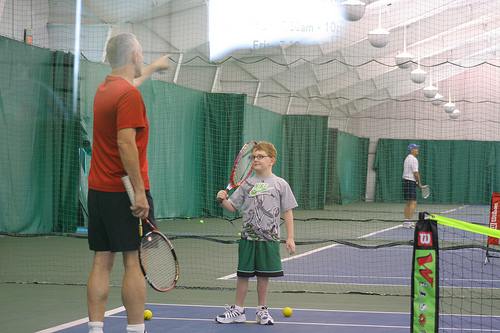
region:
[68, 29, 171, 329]
An older man wearing a red shirt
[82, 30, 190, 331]
A man holding a tennis racket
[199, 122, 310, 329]
a young boy holding a tennis racket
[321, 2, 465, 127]
a row of globe lights across a white ceiling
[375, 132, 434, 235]
a man in a white shirt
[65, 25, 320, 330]
an older man teaching a youngster about tennis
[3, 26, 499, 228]
green tarp draped along the walls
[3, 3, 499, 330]
netting forms a wall seperating areas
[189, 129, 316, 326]
a young boy with eyeglasses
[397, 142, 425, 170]
a man wearing a blue hat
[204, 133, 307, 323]
this is a boy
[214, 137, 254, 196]
the boy is holding a racket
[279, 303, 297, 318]
this is a ball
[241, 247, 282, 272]
he is wearing a short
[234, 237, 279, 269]
the short is green in color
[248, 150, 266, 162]
the boy is wearing specks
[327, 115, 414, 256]
this is a net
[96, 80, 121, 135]
the t shirt is red in color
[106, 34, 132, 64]
the hair is grey in color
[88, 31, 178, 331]
a man wearing a red shirt and black shorts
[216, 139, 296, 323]
a young boy in a grey shirt and green shorts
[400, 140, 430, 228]
a man wearing a blue ball cap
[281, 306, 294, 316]
a bright yellow tennis ball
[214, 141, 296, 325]
a young boy with red hair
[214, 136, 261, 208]
a red tennis racket with a black handle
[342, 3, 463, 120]
large lights suspended from the ceiling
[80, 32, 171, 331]
a grey haired man pointing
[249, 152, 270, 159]
a pair of black eye glasses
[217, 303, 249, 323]
a child's white tennis shoe with strings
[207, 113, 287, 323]
A boy with a racket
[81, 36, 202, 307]
A man with a racket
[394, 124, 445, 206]
A man with a racket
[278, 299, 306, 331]
A small yellow ball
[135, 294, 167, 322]
A small yellow ball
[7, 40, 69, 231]
A green tennis court wall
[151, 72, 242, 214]
A green tennis court wall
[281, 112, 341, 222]
A green tennis court wall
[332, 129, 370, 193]
A green tennis court wall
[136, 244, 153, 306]
edge fo a racket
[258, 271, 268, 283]
edge of a short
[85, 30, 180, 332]
a male tennis player pointing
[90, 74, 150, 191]
a red polo shirt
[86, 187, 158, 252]
a pair of black shorts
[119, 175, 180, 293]
a red black and white tennis racket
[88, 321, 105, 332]
a man's white sock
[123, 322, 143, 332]
a man's white sock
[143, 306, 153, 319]
a yellow tennis ball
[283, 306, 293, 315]
a yellow tennis ball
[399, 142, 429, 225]
a male tennis player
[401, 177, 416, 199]
a pair of black shorts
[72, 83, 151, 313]
A man in a red shirt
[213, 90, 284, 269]
A boy in a gray shirt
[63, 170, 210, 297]
A man holding a tennis track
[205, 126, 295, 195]
A little boy with red hair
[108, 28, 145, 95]
A man with gray hair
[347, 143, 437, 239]
A man in a white shirt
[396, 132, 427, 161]
A man in a blue hat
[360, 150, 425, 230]
A man in a white shirt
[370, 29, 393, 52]
A light handing from the ceiling.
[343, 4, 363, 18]
A light handing from the ceiling.